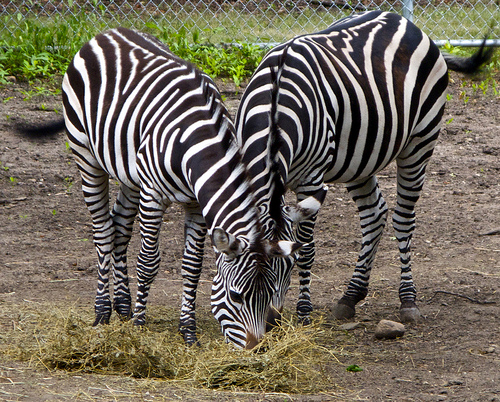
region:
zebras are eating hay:
[179, 179, 326, 398]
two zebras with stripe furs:
[59, 25, 465, 398]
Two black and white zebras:
[60, 8, 446, 355]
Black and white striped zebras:
[60, 10, 451, 355]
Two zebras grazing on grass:
[56, 8, 451, 355]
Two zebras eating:
[57, 10, 449, 350]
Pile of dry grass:
[5, 290, 346, 394]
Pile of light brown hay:
[8, 298, 348, 393]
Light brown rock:
[370, 314, 405, 341]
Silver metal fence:
[2, 0, 498, 57]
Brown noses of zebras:
[242, 298, 285, 356]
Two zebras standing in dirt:
[57, 8, 450, 354]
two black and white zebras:
[9, 8, 491, 351]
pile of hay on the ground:
[33, 313, 336, 390]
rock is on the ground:
[373, 317, 405, 339]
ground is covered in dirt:
[2, 83, 496, 400]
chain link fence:
[1, 0, 498, 50]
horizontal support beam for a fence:
[1, 35, 497, 47]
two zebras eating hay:
[13, 9, 488, 351]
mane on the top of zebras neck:
[201, 58, 260, 255]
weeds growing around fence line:
[3, 8, 498, 83]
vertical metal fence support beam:
[398, 0, 420, 26]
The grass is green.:
[193, 50, 244, 73]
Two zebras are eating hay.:
[7, 6, 487, 391]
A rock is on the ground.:
[371, 317, 406, 339]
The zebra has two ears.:
[208, 225, 304, 256]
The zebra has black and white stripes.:
[60, 25, 320, 352]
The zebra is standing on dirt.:
[231, 8, 496, 331]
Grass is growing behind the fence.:
[0, 0, 498, 51]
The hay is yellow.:
[3, 306, 329, 392]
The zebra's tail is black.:
[0, 111, 67, 141]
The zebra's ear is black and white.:
[284, 182, 339, 224]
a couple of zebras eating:
[61, 4, 450, 388]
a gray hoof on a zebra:
[325, 301, 355, 321]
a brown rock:
[373, 317, 404, 343]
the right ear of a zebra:
[204, 228, 248, 261]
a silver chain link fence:
[171, 1, 322, 31]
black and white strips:
[328, 40, 418, 138]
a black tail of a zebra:
[0, 105, 64, 150]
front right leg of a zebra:
[128, 194, 164, 326]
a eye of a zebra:
[221, 285, 250, 307]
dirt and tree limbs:
[441, 225, 499, 319]